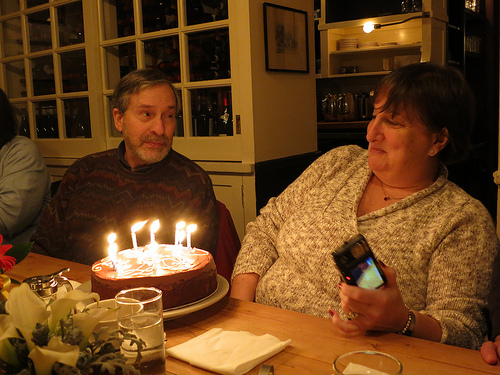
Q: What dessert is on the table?
A: A cake.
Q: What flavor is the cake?
A: Chocolate.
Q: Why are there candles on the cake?
A: Birthday celebration.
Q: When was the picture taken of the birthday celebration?
A: Nighttime.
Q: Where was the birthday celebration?
A: AT home.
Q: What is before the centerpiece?
A: Glass of water.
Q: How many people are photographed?
A: Three.